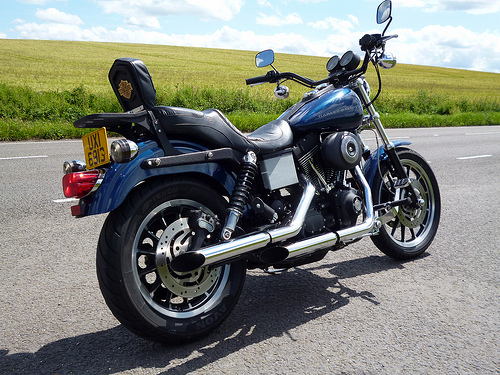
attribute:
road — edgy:
[0, 125, 499, 374]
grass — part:
[0, 38, 499, 140]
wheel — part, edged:
[95, 178, 247, 348]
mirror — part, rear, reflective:
[253, 49, 280, 68]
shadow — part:
[2, 254, 430, 374]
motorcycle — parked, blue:
[65, 1, 443, 345]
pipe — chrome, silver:
[172, 184, 318, 273]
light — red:
[62, 167, 105, 199]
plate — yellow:
[82, 128, 115, 173]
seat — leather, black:
[109, 58, 292, 154]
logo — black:
[313, 98, 365, 119]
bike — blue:
[63, 1, 440, 346]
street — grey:
[1, 124, 499, 374]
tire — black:
[367, 149, 444, 259]